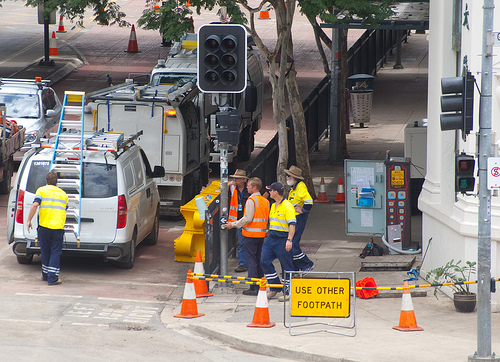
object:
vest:
[241, 194, 272, 239]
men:
[222, 168, 254, 273]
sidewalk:
[182, 0, 500, 362]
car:
[0, 76, 64, 162]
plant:
[422, 257, 477, 301]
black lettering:
[295, 286, 301, 294]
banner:
[287, 277, 352, 319]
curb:
[188, 323, 357, 362]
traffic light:
[438, 75, 465, 97]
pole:
[471, 0, 497, 359]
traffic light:
[455, 176, 476, 193]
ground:
[0, 0, 426, 362]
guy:
[23, 170, 70, 287]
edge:
[193, 324, 358, 362]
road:
[0, 0, 425, 362]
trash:
[345, 73, 378, 127]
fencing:
[192, 20, 409, 283]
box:
[343, 155, 413, 256]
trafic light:
[219, 35, 238, 54]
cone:
[173, 269, 205, 319]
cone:
[250, 277, 273, 325]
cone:
[188, 248, 214, 298]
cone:
[392, 280, 425, 331]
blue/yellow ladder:
[43, 89, 85, 248]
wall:
[425, 0, 443, 194]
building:
[413, 0, 500, 305]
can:
[345, 73, 377, 128]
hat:
[284, 165, 305, 180]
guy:
[281, 163, 317, 277]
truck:
[3, 129, 168, 271]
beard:
[286, 177, 294, 186]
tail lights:
[116, 193, 128, 230]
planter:
[452, 291, 476, 313]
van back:
[12, 155, 128, 245]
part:
[103, 254, 193, 305]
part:
[294, 286, 313, 299]